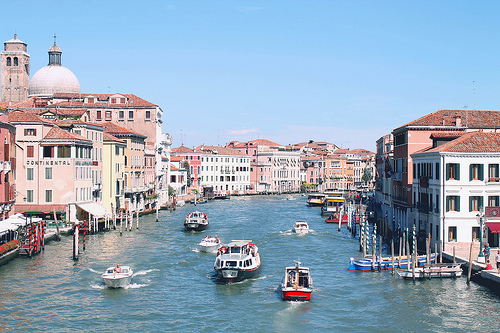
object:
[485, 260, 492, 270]
person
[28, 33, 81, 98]
dome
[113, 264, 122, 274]
man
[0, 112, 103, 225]
building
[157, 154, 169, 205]
building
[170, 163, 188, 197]
building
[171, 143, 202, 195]
building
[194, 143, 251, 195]
building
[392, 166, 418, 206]
ground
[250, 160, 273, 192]
buildings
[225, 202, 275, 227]
water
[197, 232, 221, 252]
boat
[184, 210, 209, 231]
boat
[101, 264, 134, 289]
boat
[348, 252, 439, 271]
boat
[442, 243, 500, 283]
dock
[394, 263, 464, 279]
boats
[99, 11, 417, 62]
sky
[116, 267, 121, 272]
shirt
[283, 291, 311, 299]
red bottom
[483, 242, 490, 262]
person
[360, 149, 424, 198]
ground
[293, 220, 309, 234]
boat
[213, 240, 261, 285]
boat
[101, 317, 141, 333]
water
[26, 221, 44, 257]
pylons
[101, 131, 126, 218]
building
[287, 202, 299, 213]
water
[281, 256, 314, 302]
boat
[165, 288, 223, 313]
water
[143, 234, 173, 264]
water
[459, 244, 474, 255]
deck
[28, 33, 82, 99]
steeple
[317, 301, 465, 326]
water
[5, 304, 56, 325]
water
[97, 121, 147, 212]
building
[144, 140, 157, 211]
building